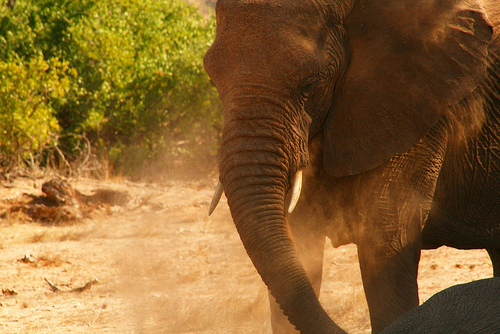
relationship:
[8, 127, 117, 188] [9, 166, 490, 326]
branches on ground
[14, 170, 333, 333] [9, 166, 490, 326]
dirt on ground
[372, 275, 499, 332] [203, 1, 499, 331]
elephant by elephant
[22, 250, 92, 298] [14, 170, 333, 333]
clump of dirt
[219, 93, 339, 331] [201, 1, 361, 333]
trunk near head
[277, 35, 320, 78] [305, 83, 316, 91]
bumps above eye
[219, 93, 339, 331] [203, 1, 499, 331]
trunk of elephant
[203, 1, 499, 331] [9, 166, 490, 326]
elephant on ground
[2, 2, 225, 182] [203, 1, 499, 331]
bush near elephant